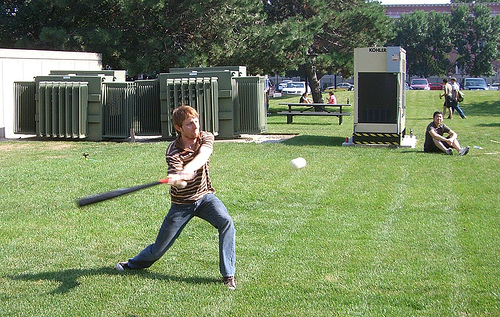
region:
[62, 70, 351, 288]
Man is swinging bat at ball.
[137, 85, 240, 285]
Man is wearing striped shirt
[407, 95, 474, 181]
Man with black hair is sitting on grass watching.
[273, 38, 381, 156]
Dark picnic table by power boxes.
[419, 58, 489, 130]
Two men walking next to each other.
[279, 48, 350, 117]
Two people sitting by tree.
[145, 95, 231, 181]
Man hitting ball has red hair.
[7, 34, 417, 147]
Large power supply boxes.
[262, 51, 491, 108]
Parking lot with trucks and cars.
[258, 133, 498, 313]
Grass is green and thick.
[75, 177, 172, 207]
the blurred bat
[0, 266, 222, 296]
the shadow on the ground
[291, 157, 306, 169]
the ball in motion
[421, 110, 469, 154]
the man sitting down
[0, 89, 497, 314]
the grass on the ground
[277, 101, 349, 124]
the picnic benches and table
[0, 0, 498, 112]
the trees in the park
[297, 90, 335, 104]
the people sitting in the background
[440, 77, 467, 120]
the people walking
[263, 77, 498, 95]
the parked cars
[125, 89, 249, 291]
this is a person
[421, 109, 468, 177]
this is a person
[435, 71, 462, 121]
this is a person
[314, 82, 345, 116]
this is a person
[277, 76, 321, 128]
this is a person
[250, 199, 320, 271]
this is a patch of grass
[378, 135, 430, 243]
this is a patch of grass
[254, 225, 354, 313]
this is a patch of grass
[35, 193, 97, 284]
this is a patch of grass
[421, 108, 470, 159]
Man sitting on the grass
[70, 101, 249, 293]
Man about to hit baseball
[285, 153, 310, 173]
White baseball in the air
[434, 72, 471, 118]
People walking on grass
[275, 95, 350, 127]
Picnic table sitting on grass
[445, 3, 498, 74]
Large tree in background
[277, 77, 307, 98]
White car in parking lot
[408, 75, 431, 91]
Red car in parking lot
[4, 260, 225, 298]
Man's shadow on grass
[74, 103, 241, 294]
Man in striped shirt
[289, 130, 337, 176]
the ball is in the air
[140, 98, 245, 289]
he is hitting the ball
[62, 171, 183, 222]
holding a black bat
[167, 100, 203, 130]
his hair is red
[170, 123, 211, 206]
his shirt is striped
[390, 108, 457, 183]
he is sitting down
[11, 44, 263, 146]
a machine is behind him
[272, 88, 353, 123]
a bench in the park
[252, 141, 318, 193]
the ball has been hit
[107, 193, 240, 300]
he is wearing jeans